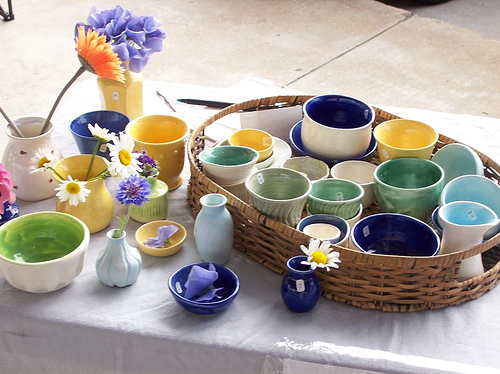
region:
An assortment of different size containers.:
[2, 7, 492, 339]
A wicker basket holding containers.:
[188, 123, 499, 315]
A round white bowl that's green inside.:
[6, 198, 93, 297]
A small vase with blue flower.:
[93, 169, 151, 285]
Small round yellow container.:
[131, 211, 189, 258]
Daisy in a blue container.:
[279, 231, 348, 318]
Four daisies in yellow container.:
[31, 134, 126, 223]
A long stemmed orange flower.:
[35, 22, 120, 121]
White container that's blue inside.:
[438, 200, 497, 287]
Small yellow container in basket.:
[208, 99, 275, 160]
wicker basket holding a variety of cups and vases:
[179, 85, 492, 316]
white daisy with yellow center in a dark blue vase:
[294, 238, 339, 273]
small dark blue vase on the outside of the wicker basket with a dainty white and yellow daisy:
[272, 230, 337, 310]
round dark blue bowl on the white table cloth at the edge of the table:
[168, 258, 244, 313]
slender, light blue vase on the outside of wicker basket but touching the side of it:
[194, 185, 237, 261]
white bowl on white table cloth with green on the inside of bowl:
[0, 214, 91, 294]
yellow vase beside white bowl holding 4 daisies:
[24, 121, 121, 231]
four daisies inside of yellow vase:
[23, 117, 131, 197]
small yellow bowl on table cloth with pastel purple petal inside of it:
[136, 214, 188, 251]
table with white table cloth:
[24, 77, 491, 363]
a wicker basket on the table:
[177, 85, 497, 305]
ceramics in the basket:
[205, 92, 492, 257]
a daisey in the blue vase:
[302, 240, 337, 267]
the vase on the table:
[270, 260, 317, 316]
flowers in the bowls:
[135, 210, 235, 310]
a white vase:
[177, 182, 237, 262]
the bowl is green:
[0, 205, 85, 290]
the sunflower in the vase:
[66, 26, 131, 87]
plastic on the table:
[271, 339, 381, 371]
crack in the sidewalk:
[317, 17, 417, 87]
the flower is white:
[289, 193, 354, 344]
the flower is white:
[272, 130, 342, 295]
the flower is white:
[261, 252, 373, 354]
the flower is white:
[295, 175, 385, 370]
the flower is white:
[288, 263, 345, 358]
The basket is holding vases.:
[184, 89, 497, 309]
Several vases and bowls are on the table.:
[0, 93, 212, 301]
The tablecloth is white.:
[0, 293, 495, 371]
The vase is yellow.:
[45, 145, 115, 240]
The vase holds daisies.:
[18, 117, 145, 211]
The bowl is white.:
[0, 200, 102, 300]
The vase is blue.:
[275, 252, 324, 321]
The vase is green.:
[362, 155, 447, 220]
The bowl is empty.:
[0, 208, 95, 300]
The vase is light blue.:
[184, 183, 241, 270]